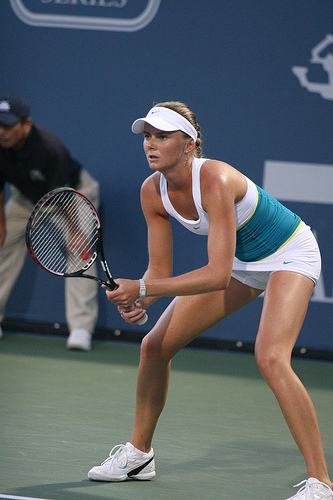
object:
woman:
[87, 99, 333, 500]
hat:
[131, 106, 199, 142]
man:
[0, 95, 100, 351]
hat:
[0, 92, 28, 127]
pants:
[0, 167, 100, 337]